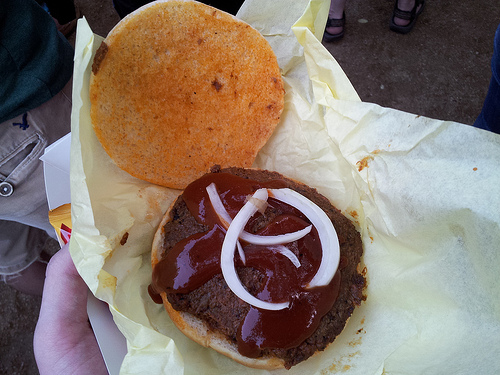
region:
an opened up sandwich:
[72, 24, 387, 361]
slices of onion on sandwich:
[203, 184, 354, 299]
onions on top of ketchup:
[195, 179, 342, 322]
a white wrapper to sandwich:
[41, 51, 498, 359]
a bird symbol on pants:
[9, 106, 44, 138]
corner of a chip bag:
[37, 189, 98, 251]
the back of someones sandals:
[326, 3, 427, 54]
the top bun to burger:
[97, 18, 314, 188]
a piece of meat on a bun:
[133, 173, 386, 374]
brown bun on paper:
[75, 27, 292, 166]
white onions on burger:
[182, 194, 337, 313]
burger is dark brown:
[188, 207, 355, 342]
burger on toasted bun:
[153, 202, 348, 329]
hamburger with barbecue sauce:
[70, 19, 357, 358]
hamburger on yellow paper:
[145, 27, 380, 359]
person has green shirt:
[4, 3, 94, 98]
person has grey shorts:
[1, 60, 82, 199]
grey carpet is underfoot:
[365, 47, 450, 106]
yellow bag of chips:
[32, 202, 90, 243]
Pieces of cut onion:
[205, 181, 340, 309]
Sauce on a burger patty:
[145, 170, 340, 356]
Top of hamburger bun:
[93, 0, 284, 190]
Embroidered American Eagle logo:
[12, 112, 31, 132]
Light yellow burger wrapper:
[72, 0, 498, 372]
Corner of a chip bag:
[45, 202, 72, 245]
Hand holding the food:
[31, 242, 140, 373]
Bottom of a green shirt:
[1, 0, 75, 121]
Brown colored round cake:
[93, 33, 277, 96]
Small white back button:
[2, 180, 16, 198]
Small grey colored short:
[7, 257, 34, 278]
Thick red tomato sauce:
[170, 238, 209, 286]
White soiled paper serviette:
[357, 139, 427, 200]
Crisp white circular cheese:
[301, 197, 328, 227]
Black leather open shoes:
[389, 3, 425, 40]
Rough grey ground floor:
[388, 55, 475, 101]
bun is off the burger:
[80, 4, 295, 179]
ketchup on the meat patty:
[146, 155, 363, 366]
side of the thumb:
[17, 235, 116, 374]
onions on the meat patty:
[199, 170, 341, 317]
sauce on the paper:
[143, 282, 163, 307]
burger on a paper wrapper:
[51, 0, 498, 373]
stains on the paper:
[316, 315, 373, 372]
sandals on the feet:
[318, 1, 425, 46]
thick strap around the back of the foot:
[389, 3, 414, 23]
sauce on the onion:
[284, 283, 308, 310]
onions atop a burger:
[221, 185, 275, 305]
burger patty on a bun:
[162, 166, 357, 333]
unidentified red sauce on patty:
[149, 168, 317, 328]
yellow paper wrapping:
[343, 92, 474, 329]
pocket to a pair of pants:
[0, 119, 42, 205]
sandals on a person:
[312, 4, 444, 47]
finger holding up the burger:
[46, 251, 95, 373]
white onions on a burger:
[279, 177, 344, 290]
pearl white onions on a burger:
[211, 176, 282, 308]